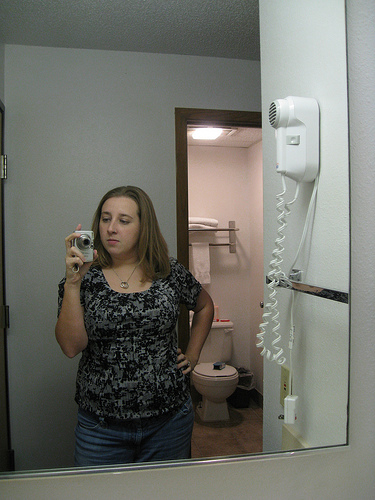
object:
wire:
[250, 193, 291, 367]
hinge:
[0, 153, 10, 181]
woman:
[56, 185, 214, 465]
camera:
[71, 232, 96, 265]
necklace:
[109, 260, 141, 291]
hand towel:
[192, 237, 210, 287]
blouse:
[57, 255, 202, 418]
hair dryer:
[269, 97, 321, 183]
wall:
[262, 0, 351, 452]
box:
[214, 358, 231, 371]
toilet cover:
[191, 361, 242, 379]